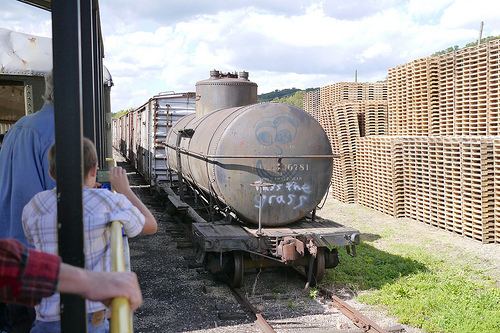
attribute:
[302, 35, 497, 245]
pallets — Stacked 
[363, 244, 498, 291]
railroad side — side 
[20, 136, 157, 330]
boy — little  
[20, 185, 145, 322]
shirt — white  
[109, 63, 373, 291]
train — long, part 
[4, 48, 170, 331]
people — small group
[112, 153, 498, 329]
ground — part 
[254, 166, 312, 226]
graffiti — white 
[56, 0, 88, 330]
pole — Metal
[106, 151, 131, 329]
rail — edge 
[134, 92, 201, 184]
boxcar — gray 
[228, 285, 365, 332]
tracks — Rusted railroad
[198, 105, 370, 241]
metal — part 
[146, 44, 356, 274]
tank — metal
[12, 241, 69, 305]
shirt — red plaid , sleef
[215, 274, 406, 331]
tracks — portion , train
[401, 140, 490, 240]
pallet stack — wooden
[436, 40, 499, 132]
pallet stack — wooden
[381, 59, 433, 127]
pallet stack — wooden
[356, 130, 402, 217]
pallet stack — wooden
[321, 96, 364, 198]
pallet stack — wooden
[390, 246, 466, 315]
grass — small patch, green 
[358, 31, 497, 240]
wood pallets — piles 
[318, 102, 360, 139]
pallet — tipping stack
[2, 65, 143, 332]
group — people 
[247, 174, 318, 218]
paint — spray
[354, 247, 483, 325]
grass — pass 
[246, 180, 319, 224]
paint — White 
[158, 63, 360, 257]
car — train